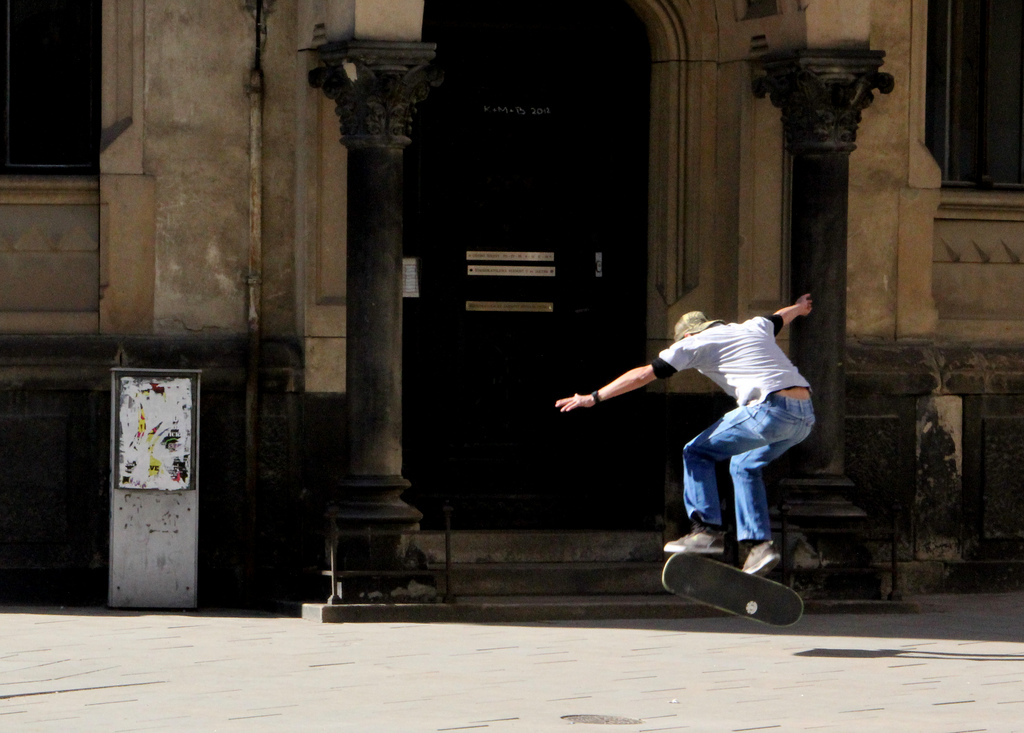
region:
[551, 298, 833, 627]
person on a skateboard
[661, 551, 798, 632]
the board is black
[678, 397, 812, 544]
the jeans are blue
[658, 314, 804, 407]
the shirt is white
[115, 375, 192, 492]
some paint is chipped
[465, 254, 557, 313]
gold bars on door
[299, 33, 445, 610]
the column is black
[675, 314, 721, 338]
the hair is blonde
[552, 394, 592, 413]
hand of a person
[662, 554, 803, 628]
Skateboard in midair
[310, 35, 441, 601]
Black ornate pillar on the left side of the door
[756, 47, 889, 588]
Black pillar on the right side of the door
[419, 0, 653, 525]
Large black door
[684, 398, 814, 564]
Man wearing blue jeans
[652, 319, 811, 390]
Man wearing white t-shirt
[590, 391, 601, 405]
Man wearing watch on his left wrist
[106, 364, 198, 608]
Beat up metal box not in use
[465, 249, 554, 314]
Gold name plates on the door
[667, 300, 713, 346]
man has blonde hair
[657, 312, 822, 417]
man has on shirt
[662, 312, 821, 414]
man's shirt is white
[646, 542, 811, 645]
man's skateboard is black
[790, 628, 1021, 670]
shadow of man on ground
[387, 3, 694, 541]
large door in archway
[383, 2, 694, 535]
large door is black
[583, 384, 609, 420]
watch on man's wrist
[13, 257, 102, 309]
a stone in a wall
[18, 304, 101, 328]
a stone in a wall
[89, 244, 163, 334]
a stone in a wall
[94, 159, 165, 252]
a stone in a wall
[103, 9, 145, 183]
a stone in a wall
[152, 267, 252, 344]
a stone in a wall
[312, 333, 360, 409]
a stone in a wall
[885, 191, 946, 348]
a stone in a wall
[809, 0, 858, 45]
a stone in a wall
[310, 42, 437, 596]
black pillar on the building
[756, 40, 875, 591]
black pillar on the building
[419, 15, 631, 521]
black door on the building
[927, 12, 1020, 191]
black window on the building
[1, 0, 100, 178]
black window on the building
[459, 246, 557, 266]
gold name plate on black door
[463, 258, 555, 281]
gold name plate on black door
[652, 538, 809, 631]
skate board on its side under the man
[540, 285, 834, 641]
a boy jumping on a skateboard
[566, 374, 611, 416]
A watch on a Wrist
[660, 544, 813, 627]
The bottom of a skateboard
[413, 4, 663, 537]
The front door of a building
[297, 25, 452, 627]
A column in front of the building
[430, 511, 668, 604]
Stairs leading to the door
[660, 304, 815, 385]
The back of a boy wearing a beige cap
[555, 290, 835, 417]
A boy with outstretched arms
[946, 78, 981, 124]
glass window on the building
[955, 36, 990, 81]
glass window on the building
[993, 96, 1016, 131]
glass window on the building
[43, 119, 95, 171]
glass window on the building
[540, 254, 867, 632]
Skater wearing blue jeans and a t shirt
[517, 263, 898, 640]
Skater performomg a trick on the sidewalk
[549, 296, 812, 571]
a person is playing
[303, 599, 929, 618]
a step on a stairway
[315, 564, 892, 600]
a step on a stairway